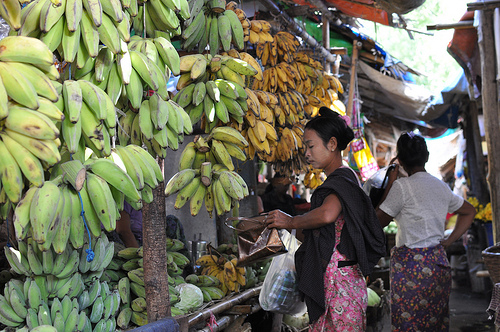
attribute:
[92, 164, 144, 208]
bananas — thick, yellow, large, green, unripened, for sale, in the market, healthy, delicious, hanging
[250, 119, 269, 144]
bananas — yellow, ripened, assorted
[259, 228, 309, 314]
bag — plastic, translucent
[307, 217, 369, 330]
garmet — pink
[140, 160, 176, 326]
trunk — wooden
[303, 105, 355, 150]
hair — dark, black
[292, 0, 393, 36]
canvas — orange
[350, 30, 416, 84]
tarp — blue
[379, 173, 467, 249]
shirt — white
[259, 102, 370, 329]
women — shopping, in marketplace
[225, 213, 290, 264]
bag — gold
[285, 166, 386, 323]
blanket — draped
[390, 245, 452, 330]
skirt — designed, patterned